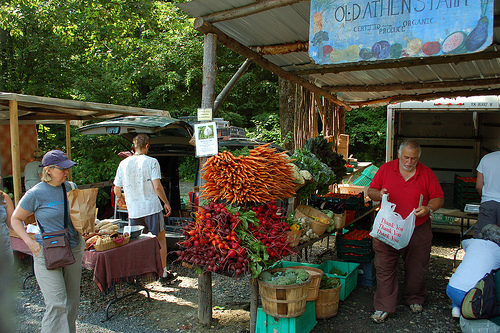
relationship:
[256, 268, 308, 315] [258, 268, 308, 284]
basket of vegetables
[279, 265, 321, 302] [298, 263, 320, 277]
basket of vegetables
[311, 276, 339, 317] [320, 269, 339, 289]
basket of vegetables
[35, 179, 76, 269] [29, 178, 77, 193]
bag over shoulder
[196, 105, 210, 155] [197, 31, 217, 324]
sign on post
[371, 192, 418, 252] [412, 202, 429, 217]
bag in hand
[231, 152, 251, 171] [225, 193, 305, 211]
carrot on shelf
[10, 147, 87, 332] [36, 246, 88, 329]
woman wearing pants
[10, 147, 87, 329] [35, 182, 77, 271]
woman carrying purse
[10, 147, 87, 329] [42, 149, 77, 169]
woman wearing cap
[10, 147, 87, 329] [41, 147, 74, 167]
woman wearing hat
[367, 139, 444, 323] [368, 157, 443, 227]
man wearing red shirt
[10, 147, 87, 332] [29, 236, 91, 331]
woman wearing pants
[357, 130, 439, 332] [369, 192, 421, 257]
man carrying plastic bag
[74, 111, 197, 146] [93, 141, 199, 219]
hatch of van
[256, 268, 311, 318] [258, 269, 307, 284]
basket of fruit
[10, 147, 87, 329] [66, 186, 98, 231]
woman carrying a bag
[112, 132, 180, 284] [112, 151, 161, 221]
man wearing a t-shirt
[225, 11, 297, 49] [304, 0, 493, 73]
metal roof with sign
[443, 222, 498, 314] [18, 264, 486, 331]
person on floor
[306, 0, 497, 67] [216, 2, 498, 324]
sign over stall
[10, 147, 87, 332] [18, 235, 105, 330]
woman wearing pants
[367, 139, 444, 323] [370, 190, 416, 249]
man carrying bag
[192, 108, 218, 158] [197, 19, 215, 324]
sign attached to wooden pole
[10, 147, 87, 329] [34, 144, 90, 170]
woman wearing cap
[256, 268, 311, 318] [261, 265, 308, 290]
basket full of vegetable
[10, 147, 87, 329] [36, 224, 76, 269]
woman carrying a purse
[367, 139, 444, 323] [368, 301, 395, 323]
man wearing shoe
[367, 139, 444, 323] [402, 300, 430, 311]
man wearing shoe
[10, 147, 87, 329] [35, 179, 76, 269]
woman wearing bag